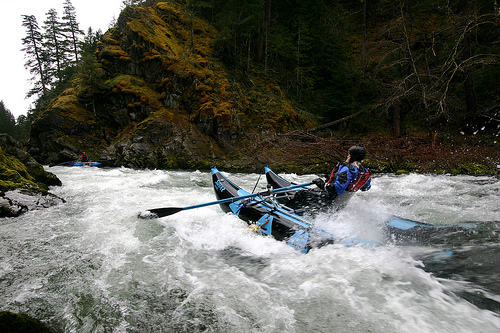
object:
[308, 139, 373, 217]
person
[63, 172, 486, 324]
river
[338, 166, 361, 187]
shirt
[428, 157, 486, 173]
vegetation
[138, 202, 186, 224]
paddle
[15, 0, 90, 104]
tree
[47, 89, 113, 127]
hill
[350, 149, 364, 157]
helmet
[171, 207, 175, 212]
black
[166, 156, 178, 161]
moss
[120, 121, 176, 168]
rock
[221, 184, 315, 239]
raft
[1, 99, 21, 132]
tree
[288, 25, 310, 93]
tree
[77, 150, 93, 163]
person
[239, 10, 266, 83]
tree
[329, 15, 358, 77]
tree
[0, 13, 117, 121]
sky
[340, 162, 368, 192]
jacket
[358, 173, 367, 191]
backpack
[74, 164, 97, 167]
raft